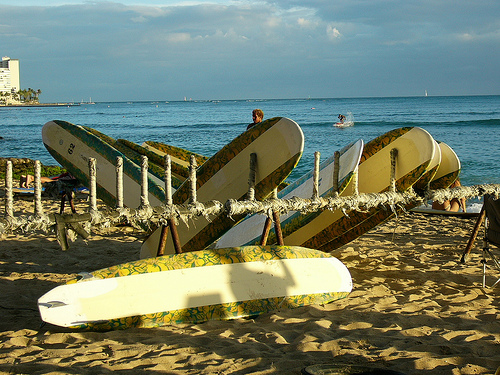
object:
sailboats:
[212, 101, 221, 105]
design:
[61, 245, 333, 286]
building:
[0, 56, 21, 107]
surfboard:
[332, 122, 354, 127]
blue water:
[1, 95, 492, 224]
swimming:
[333, 110, 356, 127]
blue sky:
[0, 0, 500, 103]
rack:
[0, 152, 500, 251]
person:
[19, 175, 53, 190]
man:
[338, 114, 346, 124]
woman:
[432, 177, 467, 213]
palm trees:
[6, 87, 42, 101]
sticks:
[0, 148, 462, 218]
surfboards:
[37, 116, 460, 334]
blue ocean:
[0, 94, 499, 213]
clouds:
[0, 0, 500, 47]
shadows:
[358, 227, 500, 253]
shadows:
[0, 306, 500, 375]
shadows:
[0, 227, 142, 280]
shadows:
[80, 328, 453, 374]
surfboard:
[138, 116, 303, 260]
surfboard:
[274, 127, 435, 250]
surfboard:
[315, 139, 442, 255]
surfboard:
[430, 140, 461, 190]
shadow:
[183, 245, 298, 326]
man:
[246, 109, 265, 131]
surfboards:
[41, 119, 210, 215]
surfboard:
[37, 245, 352, 331]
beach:
[0, 179, 499, 373]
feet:
[48, 210, 93, 251]